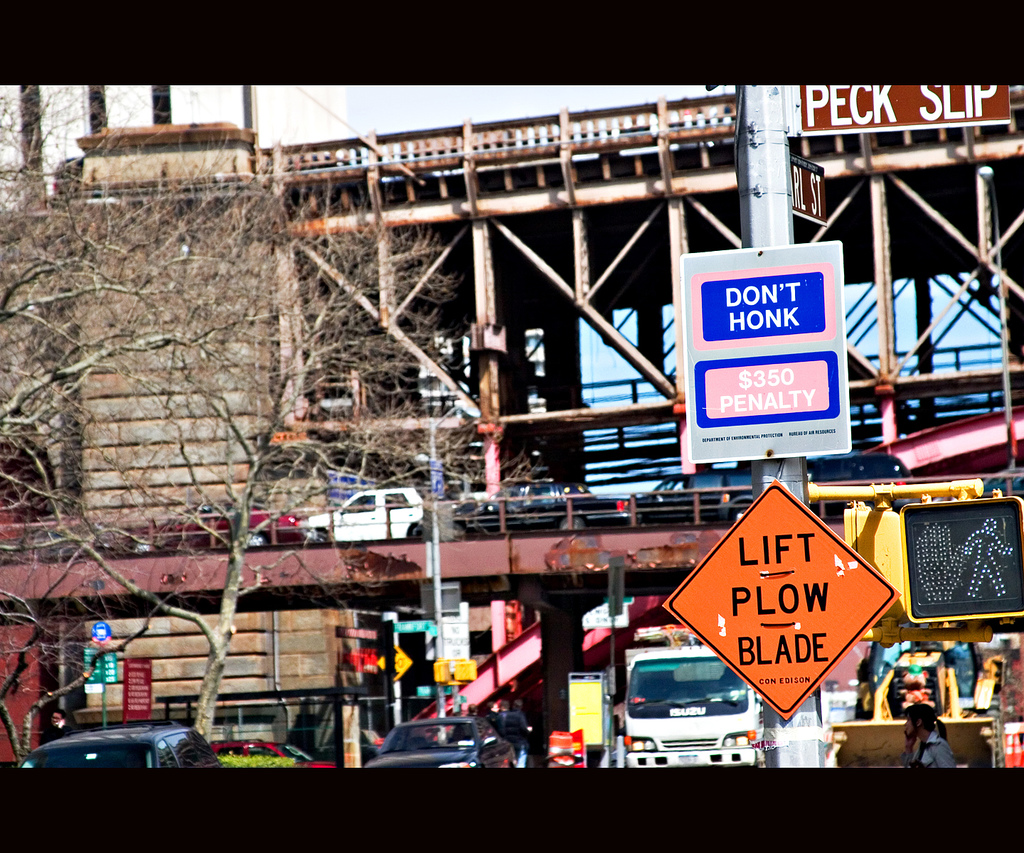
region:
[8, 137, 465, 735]
a tree with no leaves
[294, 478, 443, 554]
A white car on the bridge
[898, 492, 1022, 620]
walk, don't walk street sign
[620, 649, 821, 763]
white Isuzu moving truck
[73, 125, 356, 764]
brick support for upper bridge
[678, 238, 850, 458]
don't honk penelty sign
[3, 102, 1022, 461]
upper bridge and support area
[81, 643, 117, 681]
street sign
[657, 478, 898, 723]
orange sign, lift plow blade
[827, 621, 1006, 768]
road work equipment, backhoe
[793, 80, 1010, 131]
brown road sign, peck slip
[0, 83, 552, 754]
small tree with no leaves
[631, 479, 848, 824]
the sign is orange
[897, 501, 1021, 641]
the walk sign is off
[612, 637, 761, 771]
the truck is white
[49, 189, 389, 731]
the tree doesn't have leaves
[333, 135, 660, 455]
the railings are rusty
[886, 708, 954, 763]
the woman is talking on the phone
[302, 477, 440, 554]
the car is white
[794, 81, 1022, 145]
the street sign is maroon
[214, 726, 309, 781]
the car is red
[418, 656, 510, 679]
the stop light is yellow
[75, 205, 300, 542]
Broad column features old stonework.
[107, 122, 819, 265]
Bridge with brown railing.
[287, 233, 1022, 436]
Bridge support structure, showing cross-struts in a Y pattern.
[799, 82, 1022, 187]
Sign reads, "Peck Slip."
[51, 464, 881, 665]
Reddish metal overpass, features heavy traffic.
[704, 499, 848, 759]
Orange sign reads, "Lift Plow Blade."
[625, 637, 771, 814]
White truck-face shown, behind sign.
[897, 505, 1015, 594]
Unlit pedestrian crossing sign.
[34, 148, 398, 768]
Dry and dessicated-looking tree, no leaves shown.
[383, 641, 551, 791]
Dark car, street sign, pedestrians and stair ramp.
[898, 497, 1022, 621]
crosswalk sign for street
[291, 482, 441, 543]
white car on an overpass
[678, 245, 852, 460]
street sign advising of penalty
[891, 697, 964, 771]
woman talking on cell phone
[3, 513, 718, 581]
overpass of busy street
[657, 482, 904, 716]
street sign advising of construction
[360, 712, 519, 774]
vehicle parked on the side of the road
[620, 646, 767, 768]
large white moving truck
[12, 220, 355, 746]
tree on the side of the road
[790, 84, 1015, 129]
street sign advising of street name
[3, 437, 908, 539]
cars on a bridge or overpass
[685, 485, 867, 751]
orange sign on a pole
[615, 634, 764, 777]
white truck inward bound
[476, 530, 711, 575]
chipping red paint on overpass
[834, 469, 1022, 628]
pedestrian traffic instruction near orange sign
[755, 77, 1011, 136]
dark street sign on pole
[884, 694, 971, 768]
woman appears to be holding something up to her face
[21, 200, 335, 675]
trees devoid of leaves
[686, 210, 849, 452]
sign warning people not to honk on silver pole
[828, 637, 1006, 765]
a construction vehicle behind the woman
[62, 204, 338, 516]
Tree branches with no leaves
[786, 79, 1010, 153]
Sign that reads "PECK SLIP"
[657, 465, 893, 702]
An orange sign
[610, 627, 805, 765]
Front of a white truck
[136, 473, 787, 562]
Cars lined up together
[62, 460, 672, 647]
Cars on a bridge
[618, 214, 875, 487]
A blue and white sign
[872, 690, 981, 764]
A woman has a ponytail